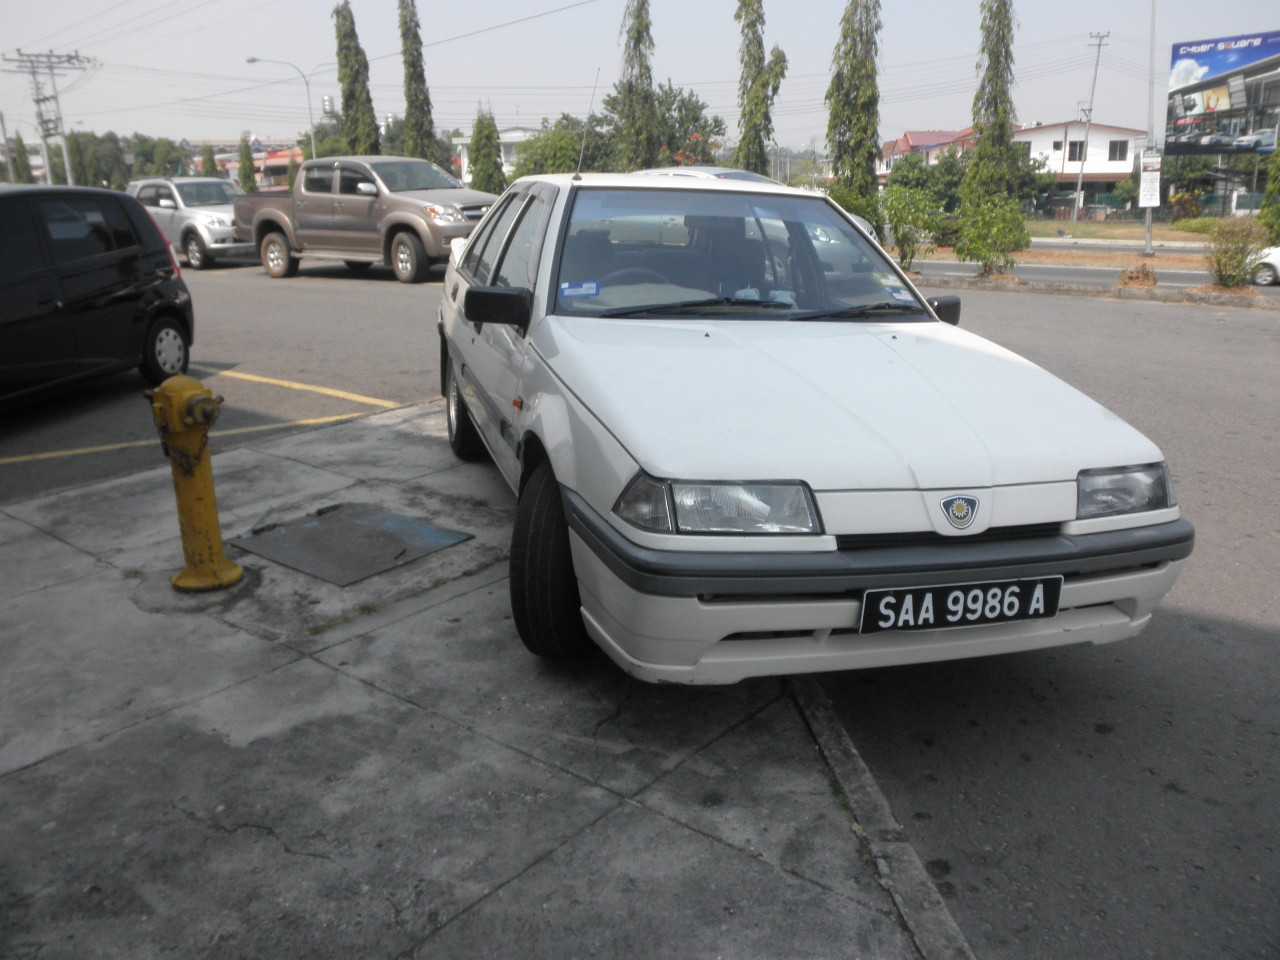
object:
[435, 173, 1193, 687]
car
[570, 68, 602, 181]
antenna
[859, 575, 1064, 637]
plate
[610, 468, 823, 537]
light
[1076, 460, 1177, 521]
light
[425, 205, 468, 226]
light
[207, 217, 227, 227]
light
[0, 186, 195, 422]
car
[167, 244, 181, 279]
light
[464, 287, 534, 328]
mirror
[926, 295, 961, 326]
mirror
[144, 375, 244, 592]
hydrant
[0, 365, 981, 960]
sidewalk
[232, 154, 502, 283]
truck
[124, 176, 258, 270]
car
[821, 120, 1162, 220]
house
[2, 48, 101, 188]
pole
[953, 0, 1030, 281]
tree